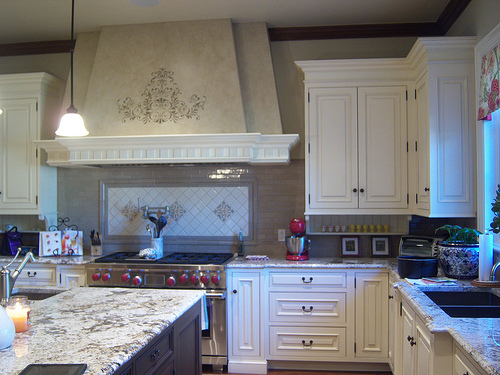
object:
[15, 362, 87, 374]
tablet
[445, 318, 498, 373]
marble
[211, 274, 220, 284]
knobs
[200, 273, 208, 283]
knobs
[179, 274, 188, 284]
knobs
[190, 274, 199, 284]
knobs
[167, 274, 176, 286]
knobs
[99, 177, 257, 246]
tiles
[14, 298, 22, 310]
flame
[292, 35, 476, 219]
cabinets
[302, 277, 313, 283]
handles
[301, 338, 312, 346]
handles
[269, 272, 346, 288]
drawers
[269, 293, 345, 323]
drawers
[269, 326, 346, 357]
drawers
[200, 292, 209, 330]
towel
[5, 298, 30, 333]
candle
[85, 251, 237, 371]
oven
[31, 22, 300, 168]
hood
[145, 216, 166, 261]
fixture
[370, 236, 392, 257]
many boats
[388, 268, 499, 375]
counter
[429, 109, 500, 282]
light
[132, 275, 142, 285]
red knob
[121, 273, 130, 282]
red knob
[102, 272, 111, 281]
red knob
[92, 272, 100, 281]
red knob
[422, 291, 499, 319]
basin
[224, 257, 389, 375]
cabinets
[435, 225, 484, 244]
plant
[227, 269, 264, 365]
cupboard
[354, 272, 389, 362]
cupboard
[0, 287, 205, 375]
counter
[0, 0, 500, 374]
kitchen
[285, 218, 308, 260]
coffee pot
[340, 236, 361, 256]
frames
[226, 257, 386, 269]
countertop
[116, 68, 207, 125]
decoration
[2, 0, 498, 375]
cabinets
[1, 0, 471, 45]
ceiling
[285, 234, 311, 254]
bowl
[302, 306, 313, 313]
handles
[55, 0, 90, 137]
fixture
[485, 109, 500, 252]
window